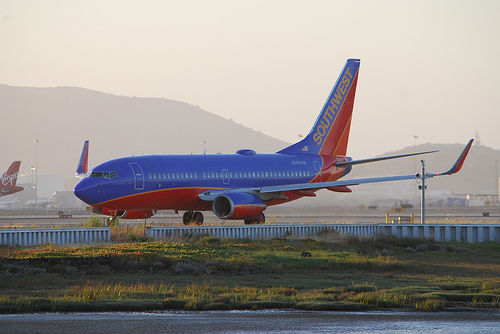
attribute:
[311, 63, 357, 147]
airplane name — yellow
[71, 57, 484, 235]
airplane — red, blue